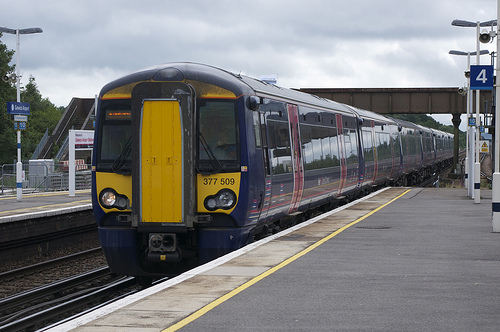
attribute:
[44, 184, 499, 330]
pavement — cement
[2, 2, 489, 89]
clouds — white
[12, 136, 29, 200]
pole — white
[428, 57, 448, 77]
clouds — white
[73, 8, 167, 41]
cloud — white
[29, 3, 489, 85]
sky — blue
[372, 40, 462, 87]
cloud — white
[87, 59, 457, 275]
train — black, yellow, big, long, passenger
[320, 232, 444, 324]
cement area — gray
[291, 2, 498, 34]
cloud — white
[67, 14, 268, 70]
cloud — white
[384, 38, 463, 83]
cloud — white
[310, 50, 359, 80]
cloud — white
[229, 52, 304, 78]
cloud — white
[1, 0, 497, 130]
sky — blue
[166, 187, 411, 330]
line — yellow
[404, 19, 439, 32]
clouds — white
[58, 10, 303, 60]
clouds — white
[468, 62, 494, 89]
sign — blue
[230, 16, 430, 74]
clouds — white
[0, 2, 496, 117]
sky — blue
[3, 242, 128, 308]
tracks — train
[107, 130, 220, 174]
windshield wipes — black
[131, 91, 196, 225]
door — yellow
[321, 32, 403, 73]
clouds — white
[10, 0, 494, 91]
sky — blue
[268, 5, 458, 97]
clouds — white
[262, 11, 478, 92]
sky — blue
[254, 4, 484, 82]
sky — blue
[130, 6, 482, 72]
sky — blue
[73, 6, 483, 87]
clouds — white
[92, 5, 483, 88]
sky — blue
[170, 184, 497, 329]
pavement — gray